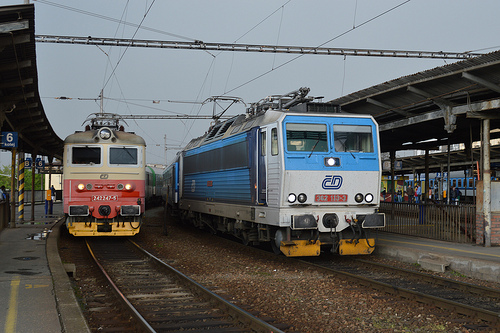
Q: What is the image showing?
A: It is showing a station.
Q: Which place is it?
A: It is a station.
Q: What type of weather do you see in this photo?
A: It is overcast.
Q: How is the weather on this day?
A: It is overcast.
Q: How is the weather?
A: It is overcast.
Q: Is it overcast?
A: Yes, it is overcast.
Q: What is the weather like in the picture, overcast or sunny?
A: It is overcast.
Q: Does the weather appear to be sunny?
A: No, it is overcast.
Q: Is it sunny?
A: No, it is overcast.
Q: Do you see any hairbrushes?
A: No, there are no hairbrushes.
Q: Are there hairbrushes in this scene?
A: No, there are no hairbrushes.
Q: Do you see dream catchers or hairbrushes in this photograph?
A: No, there are no hairbrushes or dream catchers.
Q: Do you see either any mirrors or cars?
A: No, there are no cars or mirrors.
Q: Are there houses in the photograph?
A: No, there are no houses.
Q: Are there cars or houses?
A: No, there are no houses or cars.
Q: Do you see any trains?
A: Yes, there is a train.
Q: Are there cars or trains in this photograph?
A: Yes, there is a train.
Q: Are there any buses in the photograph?
A: No, there are no buses.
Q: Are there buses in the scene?
A: No, there are no buses.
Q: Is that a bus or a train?
A: That is a train.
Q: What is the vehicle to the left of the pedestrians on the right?
A: The vehicle is a train.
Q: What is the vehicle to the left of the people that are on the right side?
A: The vehicle is a train.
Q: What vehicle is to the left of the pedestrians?
A: The vehicle is a train.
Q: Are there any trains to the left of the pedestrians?
A: Yes, there is a train to the left of the pedestrians.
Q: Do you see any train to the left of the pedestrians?
A: Yes, there is a train to the left of the pedestrians.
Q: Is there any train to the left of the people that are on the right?
A: Yes, there is a train to the left of the pedestrians.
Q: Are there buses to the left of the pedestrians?
A: No, there is a train to the left of the pedestrians.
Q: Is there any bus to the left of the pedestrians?
A: No, there is a train to the left of the pedestrians.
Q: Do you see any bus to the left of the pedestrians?
A: No, there is a train to the left of the pedestrians.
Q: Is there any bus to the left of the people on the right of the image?
A: No, there is a train to the left of the pedestrians.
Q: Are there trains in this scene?
A: Yes, there is a train.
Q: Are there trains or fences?
A: Yes, there is a train.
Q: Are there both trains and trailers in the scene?
A: No, there is a train but no trailers.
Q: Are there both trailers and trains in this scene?
A: No, there is a train but no trailers.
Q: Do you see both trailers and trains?
A: No, there is a train but no trailers.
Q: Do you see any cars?
A: No, there are no cars.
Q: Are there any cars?
A: No, there are no cars.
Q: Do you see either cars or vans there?
A: No, there are no cars or vans.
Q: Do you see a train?
A: Yes, there is a train.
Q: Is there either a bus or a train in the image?
A: Yes, there is a train.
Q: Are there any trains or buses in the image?
A: Yes, there is a train.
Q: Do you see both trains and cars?
A: No, there is a train but no cars.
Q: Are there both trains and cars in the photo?
A: No, there is a train but no cars.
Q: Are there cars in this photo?
A: No, there are no cars.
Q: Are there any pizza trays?
A: No, there are no pizza trays.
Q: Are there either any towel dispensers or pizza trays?
A: No, there are no pizza trays or towel dispensers.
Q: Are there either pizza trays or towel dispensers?
A: No, there are no pizza trays or towel dispensers.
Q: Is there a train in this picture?
A: Yes, there is a train.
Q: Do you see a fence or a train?
A: Yes, there is a train.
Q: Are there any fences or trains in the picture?
A: Yes, there is a train.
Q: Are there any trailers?
A: No, there are no trailers.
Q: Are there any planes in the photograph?
A: No, there are no planes.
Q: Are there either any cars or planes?
A: No, there are no planes or cars.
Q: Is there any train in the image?
A: Yes, there is a train.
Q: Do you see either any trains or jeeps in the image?
A: Yes, there is a train.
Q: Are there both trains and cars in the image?
A: No, there is a train but no cars.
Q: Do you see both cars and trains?
A: No, there is a train but no cars.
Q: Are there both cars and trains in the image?
A: No, there is a train but no cars.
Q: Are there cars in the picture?
A: No, there are no cars.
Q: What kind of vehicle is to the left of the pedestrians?
A: The vehicle is a train.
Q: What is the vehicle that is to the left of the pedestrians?
A: The vehicle is a train.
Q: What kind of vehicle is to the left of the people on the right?
A: The vehicle is a train.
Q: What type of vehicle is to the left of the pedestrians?
A: The vehicle is a train.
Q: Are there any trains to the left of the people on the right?
A: Yes, there is a train to the left of the pedestrians.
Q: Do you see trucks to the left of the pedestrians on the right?
A: No, there is a train to the left of the pedestrians.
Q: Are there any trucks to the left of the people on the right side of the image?
A: No, there is a train to the left of the pedestrians.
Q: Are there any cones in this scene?
A: No, there are no cones.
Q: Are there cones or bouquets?
A: No, there are no cones or bouquets.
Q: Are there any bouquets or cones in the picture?
A: No, there are no cones or bouquets.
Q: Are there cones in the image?
A: No, there are no cones.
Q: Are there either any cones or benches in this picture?
A: No, there are no cones or benches.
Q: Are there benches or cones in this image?
A: No, there are no cones or benches.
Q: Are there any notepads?
A: No, there are no notepads.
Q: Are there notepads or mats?
A: No, there are no notepads or mats.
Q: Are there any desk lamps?
A: No, there are no desk lamps.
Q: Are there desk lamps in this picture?
A: No, there are no desk lamps.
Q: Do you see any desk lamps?
A: No, there are no desk lamps.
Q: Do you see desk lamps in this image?
A: No, there are no desk lamps.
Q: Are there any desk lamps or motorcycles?
A: No, there are no desk lamps or motorcycles.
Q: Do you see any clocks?
A: No, there are no clocks.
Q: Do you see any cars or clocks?
A: No, there are no clocks or cars.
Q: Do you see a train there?
A: Yes, there are trains.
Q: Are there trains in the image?
A: Yes, there are trains.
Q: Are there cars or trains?
A: Yes, there are trains.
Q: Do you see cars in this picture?
A: No, there are no cars.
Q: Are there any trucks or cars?
A: No, there are no cars or trucks.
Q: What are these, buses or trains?
A: These are trains.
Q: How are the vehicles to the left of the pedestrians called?
A: The vehicles are trains.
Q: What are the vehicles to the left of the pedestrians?
A: The vehicles are trains.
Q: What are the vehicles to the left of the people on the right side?
A: The vehicles are trains.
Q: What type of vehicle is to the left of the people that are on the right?
A: The vehicles are trains.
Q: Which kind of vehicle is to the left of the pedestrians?
A: The vehicles are trains.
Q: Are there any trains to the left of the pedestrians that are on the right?
A: Yes, there are trains to the left of the pedestrians.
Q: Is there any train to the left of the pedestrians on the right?
A: Yes, there are trains to the left of the pedestrians.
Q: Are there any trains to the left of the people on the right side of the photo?
A: Yes, there are trains to the left of the pedestrians.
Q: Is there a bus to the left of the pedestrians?
A: No, there are trains to the left of the pedestrians.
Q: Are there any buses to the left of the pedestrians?
A: No, there are trains to the left of the pedestrians.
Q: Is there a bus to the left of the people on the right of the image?
A: No, there are trains to the left of the pedestrians.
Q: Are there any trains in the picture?
A: Yes, there is a train.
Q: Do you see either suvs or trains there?
A: Yes, there is a train.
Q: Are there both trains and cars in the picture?
A: No, there is a train but no cars.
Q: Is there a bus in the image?
A: No, there are no buses.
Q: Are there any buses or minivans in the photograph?
A: No, there are no buses or minivans.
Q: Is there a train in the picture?
A: Yes, there is a train.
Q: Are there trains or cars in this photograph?
A: Yes, there is a train.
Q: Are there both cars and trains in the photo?
A: No, there is a train but no cars.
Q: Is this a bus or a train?
A: This is a train.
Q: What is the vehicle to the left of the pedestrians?
A: The vehicle is a train.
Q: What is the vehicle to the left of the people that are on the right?
A: The vehicle is a train.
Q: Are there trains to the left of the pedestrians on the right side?
A: Yes, there is a train to the left of the pedestrians.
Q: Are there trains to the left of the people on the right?
A: Yes, there is a train to the left of the pedestrians.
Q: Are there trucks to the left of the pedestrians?
A: No, there is a train to the left of the pedestrians.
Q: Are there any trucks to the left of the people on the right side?
A: No, there is a train to the left of the pedestrians.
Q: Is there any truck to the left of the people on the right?
A: No, there is a train to the left of the pedestrians.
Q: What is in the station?
A: The train is in the station.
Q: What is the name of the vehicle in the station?
A: The vehicle is a train.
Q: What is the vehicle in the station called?
A: The vehicle is a train.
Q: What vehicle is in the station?
A: The vehicle is a train.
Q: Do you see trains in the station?
A: Yes, there is a train in the station.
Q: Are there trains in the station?
A: Yes, there is a train in the station.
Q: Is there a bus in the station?
A: No, there is a train in the station.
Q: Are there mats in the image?
A: No, there are no mats.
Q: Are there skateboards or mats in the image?
A: No, there are no mats or skateboards.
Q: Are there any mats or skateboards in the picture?
A: No, there are no mats or skateboards.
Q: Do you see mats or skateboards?
A: No, there are no mats or skateboards.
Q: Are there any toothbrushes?
A: No, there are no toothbrushes.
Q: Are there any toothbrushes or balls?
A: No, there are no toothbrushes or balls.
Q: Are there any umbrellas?
A: No, there are no umbrellas.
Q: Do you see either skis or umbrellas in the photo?
A: No, there are no umbrellas or skis.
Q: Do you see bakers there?
A: No, there are no bakers.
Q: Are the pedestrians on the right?
A: Yes, the pedestrians are on the right of the image.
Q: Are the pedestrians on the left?
A: No, the pedestrians are on the right of the image.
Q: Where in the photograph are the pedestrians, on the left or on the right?
A: The pedestrians are on the right of the image.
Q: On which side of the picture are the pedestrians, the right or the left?
A: The pedestrians are on the right of the image.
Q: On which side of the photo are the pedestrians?
A: The pedestrians are on the right of the image.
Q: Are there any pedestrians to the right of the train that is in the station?
A: Yes, there are pedestrians to the right of the train.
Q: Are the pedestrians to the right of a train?
A: Yes, the pedestrians are to the right of a train.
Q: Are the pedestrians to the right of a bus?
A: No, the pedestrians are to the right of a train.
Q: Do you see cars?
A: No, there are no cars.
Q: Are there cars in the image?
A: No, there are no cars.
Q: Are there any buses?
A: No, there are no buses.